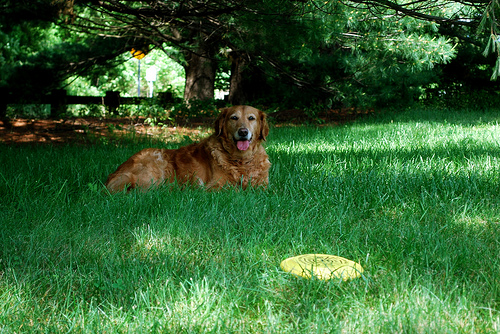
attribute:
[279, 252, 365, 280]
frisbee — yellow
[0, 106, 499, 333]
grass — green, lush, full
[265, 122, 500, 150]
spot — white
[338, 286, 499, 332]
spot — white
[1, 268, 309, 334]
spot — white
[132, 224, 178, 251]
spot — white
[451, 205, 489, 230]
spot — white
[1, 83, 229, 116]
fence — long, short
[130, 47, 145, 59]
road sign — yellow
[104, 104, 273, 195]
dog — large, brown, front facing, furry, laying, reclined, panting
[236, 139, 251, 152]
tongue — wagging, pink, out, sticking out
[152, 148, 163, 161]
spot — white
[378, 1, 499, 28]
branch — long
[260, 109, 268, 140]
ear — floppy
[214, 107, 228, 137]
ear — floppy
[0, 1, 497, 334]
scene — outdoors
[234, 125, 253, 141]
snout — white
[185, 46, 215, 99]
trunk — thick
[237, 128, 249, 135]
nose — black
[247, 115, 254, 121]
eye — dark, open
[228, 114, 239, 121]
eye — dark, open